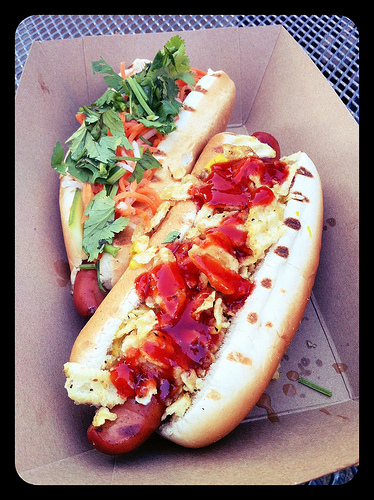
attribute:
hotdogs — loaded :
[59, 67, 326, 418]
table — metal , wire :
[13, 13, 362, 122]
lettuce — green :
[65, 33, 186, 200]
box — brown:
[14, 23, 359, 486]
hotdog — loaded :
[72, 235, 108, 318]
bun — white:
[70, 133, 318, 445]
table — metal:
[16, 17, 359, 110]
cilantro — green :
[76, 115, 124, 151]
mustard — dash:
[197, 141, 289, 185]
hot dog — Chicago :
[82, 397, 161, 458]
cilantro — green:
[49, 34, 197, 264]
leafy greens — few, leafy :
[51, 32, 198, 259]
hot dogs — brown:
[41, 51, 317, 458]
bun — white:
[57, 58, 239, 282]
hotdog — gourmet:
[63, 124, 325, 454]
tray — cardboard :
[32, 73, 361, 409]